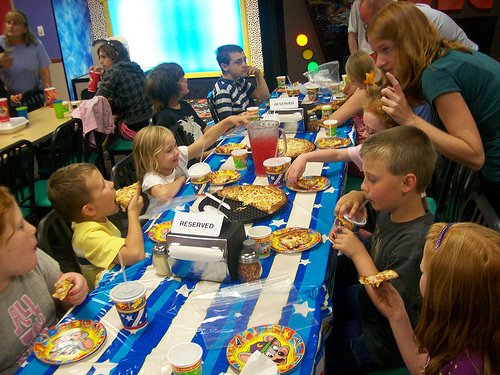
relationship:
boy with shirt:
[45, 162, 145, 293] [68, 221, 127, 286]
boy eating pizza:
[45, 162, 145, 293] [111, 178, 141, 213]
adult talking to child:
[354, 1, 483, 171] [130, 109, 266, 206]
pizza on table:
[211, 182, 291, 214] [14, 77, 374, 372]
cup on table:
[254, 150, 294, 193] [14, 77, 374, 372]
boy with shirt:
[206, 41, 271, 124] [208, 73, 256, 119]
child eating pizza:
[353, 216, 483, 373] [357, 263, 399, 290]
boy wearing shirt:
[212, 44, 271, 121] [210, 76, 255, 122]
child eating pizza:
[357, 220, 500, 375] [357, 268, 403, 288]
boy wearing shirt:
[42, 158, 153, 288] [63, 215, 129, 291]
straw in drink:
[17, 32, 67, 89] [34, 90, 74, 110]